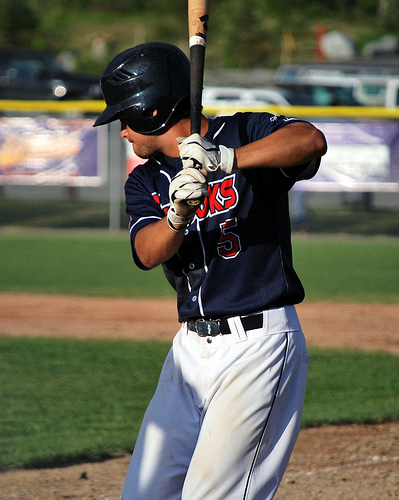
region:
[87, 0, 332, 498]
baseball batter holding bat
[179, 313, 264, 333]
black belt of baseball uniform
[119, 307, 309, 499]
white pants of baseball uniform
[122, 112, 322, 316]
navy blue baseball shirt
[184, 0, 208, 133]
wood baseball bat with black handle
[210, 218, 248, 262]
player's number on shirt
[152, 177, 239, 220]
red lettering on baseball shirt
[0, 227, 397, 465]
green grass of baseball diamond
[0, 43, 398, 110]
cars parked outside baseball diamond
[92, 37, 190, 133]
batting helmet on player's head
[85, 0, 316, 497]
this is a baseball player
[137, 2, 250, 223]
the player is holding a bat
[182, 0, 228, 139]
the bat is brown and black in color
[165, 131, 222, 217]
he has white gloves on his hands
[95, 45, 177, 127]
he is wearing helmet on his head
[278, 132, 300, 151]
the man is light skinned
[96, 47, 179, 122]
the helmet is black in color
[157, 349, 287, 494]
the player has white trousers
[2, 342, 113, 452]
the pitch is green in color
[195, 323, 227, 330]
he is having belt on waiste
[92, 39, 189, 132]
a baseball batter's helmet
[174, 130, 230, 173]
a batter's gloves are white and black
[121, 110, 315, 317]
the batter's baseball jersey is black with white trim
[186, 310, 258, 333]
the batter's belt is black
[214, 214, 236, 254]
the number five is embroidered on the batter's jersey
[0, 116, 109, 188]
there is advertising on the outfield wall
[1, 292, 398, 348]
the infield base running lane is red clay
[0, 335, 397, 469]
the fielding area of the baseball field is grass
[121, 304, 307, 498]
the baseball players pants are white with black trim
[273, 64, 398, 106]
some cars are parked behind the outfield wall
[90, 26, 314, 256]
the man is holding a bat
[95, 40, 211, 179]
the man is wearing a helmet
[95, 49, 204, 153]
the helmet is black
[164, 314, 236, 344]
the belt is black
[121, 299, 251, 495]
the pants are white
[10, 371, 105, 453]
the grass is green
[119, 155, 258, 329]
the shirt is blue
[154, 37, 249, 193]
the gloves are white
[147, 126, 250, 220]
the man is wearing gloves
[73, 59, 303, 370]
the man is wearing a belt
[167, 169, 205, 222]
one right hand baseball glove clenched.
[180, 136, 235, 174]
one left hand baseball glove clenched.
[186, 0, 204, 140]
wooden baseball bat with dark coloring.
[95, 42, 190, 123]
a black baseball helmet.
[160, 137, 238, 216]
Two white baseball gloves holding a bat.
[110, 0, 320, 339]
a baseball player holding a baseball bat.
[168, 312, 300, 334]
one black belt on baseball uniform.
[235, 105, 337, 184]
the left elbow of a man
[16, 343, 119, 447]
green grass patch on a field.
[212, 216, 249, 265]
a red number "5" on a uniform.